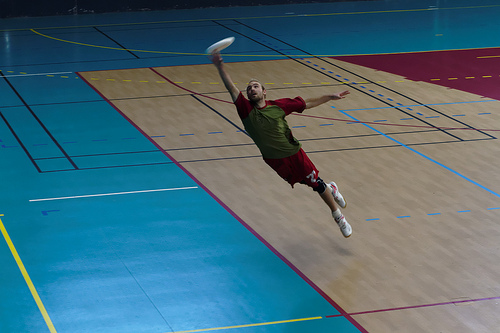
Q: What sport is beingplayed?
A: Frisebee.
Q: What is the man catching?
A: A frisbee.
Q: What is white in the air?
A: A frisbee.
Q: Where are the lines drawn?
A: On the floor.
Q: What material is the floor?
A: Wood.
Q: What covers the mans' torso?
A: A shirt?.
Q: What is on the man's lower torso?
A: Shorts.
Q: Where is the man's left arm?
A: In the air.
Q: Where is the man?
A: A gymnasium.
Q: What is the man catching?
A: A Frisbee.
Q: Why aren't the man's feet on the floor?
A: He's jumping to catch a frisbee.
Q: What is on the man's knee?
A: Knee pad.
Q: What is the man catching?
A: Frisbee.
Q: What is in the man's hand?
A: Frisbee.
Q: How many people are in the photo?
A: One.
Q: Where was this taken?
A: In a gym.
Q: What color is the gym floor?
A: Blue, tan and red.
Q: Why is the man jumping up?
A: To catch the frisbee.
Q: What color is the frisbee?
A: White.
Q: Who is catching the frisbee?
A: A man.